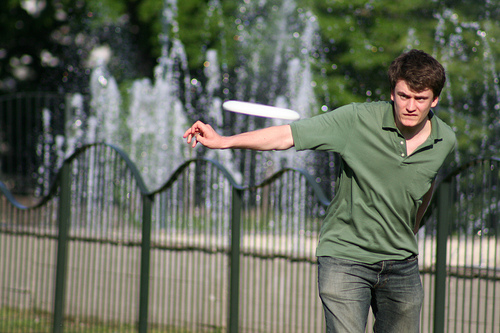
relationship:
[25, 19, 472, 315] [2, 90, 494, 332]
fountain behind fence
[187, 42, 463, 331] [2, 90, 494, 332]
man near fence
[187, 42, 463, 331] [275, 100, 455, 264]
man in shirt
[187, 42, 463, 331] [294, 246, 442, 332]
man in jeans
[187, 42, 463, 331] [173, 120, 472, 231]
man has arms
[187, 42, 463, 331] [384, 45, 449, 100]
man has hair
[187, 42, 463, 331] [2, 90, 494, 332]
man behind fence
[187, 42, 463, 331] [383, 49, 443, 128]
man has head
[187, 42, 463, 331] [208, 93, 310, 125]
man with frisbee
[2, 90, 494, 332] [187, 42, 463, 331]
fence near man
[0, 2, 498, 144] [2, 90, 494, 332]
trees behind fence